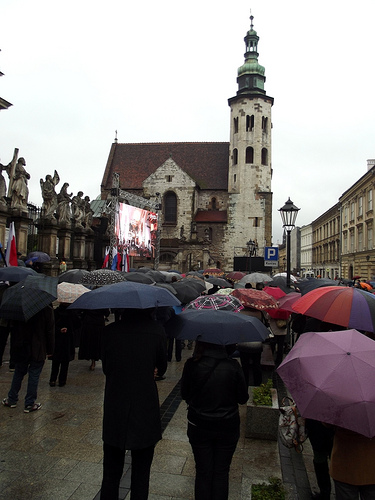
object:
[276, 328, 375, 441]
umbrellas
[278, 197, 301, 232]
lamp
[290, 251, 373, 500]
street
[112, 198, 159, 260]
screen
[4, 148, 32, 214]
statue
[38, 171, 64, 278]
statue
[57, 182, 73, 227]
statue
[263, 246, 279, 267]
sign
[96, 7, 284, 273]
building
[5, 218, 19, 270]
flag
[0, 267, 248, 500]
sidewalk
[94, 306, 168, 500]
people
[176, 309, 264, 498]
person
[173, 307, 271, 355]
umbrella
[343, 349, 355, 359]
circle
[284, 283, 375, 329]
umbrella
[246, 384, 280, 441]
planter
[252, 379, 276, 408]
plant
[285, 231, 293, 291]
post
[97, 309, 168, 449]
jacket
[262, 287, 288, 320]
umbrella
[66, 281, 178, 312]
umbrella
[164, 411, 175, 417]
tiles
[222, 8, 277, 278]
tower